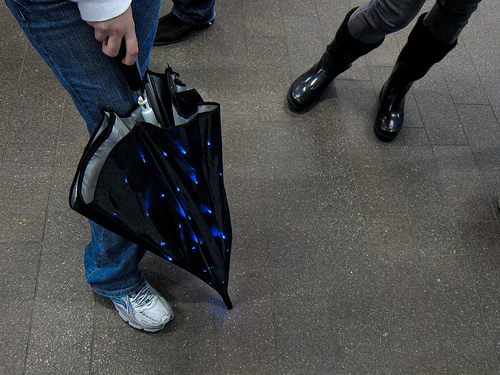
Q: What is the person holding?
A: Umbrella.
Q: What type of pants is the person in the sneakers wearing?
A: Blue jeans.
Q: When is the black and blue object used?
A: When it's raining.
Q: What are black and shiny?
A: The boots.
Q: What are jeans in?
A: Pair.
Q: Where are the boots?
A: On woman.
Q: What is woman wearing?
A: Gray pants.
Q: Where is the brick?
A: On floor.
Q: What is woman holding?
A: Umbrella.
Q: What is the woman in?
A: Jeans.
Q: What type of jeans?
A: Blue.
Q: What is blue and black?
A: Umbrella.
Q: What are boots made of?
A: Rubber.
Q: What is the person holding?
A: An umbrella.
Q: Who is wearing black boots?
A: A woman.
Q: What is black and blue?
A: The umbrella.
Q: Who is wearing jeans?
A: A woman.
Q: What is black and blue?
A: Umbrella.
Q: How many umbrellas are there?
A: One.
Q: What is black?
A: Boots.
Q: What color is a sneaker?
A: White.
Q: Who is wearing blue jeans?
A: Person on left.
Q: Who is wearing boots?
A: Person on right.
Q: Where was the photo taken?
A: On the sidewalk.